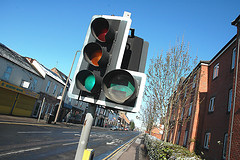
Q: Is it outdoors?
A: Yes, it is outdoors.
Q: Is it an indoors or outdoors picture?
A: It is outdoors.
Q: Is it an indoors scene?
A: No, it is outdoors.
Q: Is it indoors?
A: No, it is outdoors.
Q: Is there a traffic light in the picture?
A: Yes, there is a traffic light.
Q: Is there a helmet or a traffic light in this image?
A: Yes, there is a traffic light.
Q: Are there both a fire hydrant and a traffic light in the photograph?
A: No, there is a traffic light but no fire hydrants.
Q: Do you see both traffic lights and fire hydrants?
A: No, there is a traffic light but no fire hydrants.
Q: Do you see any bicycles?
A: No, there are no bicycles.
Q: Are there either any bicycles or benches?
A: No, there are no bicycles or benches.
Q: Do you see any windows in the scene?
A: Yes, there is a window.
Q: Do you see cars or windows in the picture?
A: Yes, there is a window.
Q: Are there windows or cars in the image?
A: Yes, there is a window.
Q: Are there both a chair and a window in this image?
A: No, there is a window but no chairs.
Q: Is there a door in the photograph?
A: No, there are no doors.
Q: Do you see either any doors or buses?
A: No, there are no doors or buses.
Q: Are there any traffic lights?
A: Yes, there is a traffic light.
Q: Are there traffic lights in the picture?
A: Yes, there is a traffic light.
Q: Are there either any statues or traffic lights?
A: Yes, there is a traffic light.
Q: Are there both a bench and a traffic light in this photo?
A: No, there is a traffic light but no benches.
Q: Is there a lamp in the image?
A: No, there are no lamps.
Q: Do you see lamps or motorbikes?
A: No, there are no lamps or motorbikes.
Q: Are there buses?
A: No, there are no buses.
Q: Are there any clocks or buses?
A: No, there are no buses or clocks.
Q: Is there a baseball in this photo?
A: No, there are no baseballs.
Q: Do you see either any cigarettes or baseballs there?
A: No, there are no baseballs or cigarettes.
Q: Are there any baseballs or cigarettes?
A: No, there are no baseballs or cigarettes.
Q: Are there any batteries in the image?
A: No, there are no batteries.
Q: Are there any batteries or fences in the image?
A: No, there are no batteries or fences.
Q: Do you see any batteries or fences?
A: No, there are no batteries or fences.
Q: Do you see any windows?
A: Yes, there is a window.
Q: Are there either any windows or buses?
A: Yes, there is a window.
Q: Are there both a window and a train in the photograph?
A: No, there is a window but no trains.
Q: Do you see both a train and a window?
A: No, there is a window but no trains.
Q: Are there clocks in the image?
A: No, there are no clocks.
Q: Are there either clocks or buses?
A: No, there are no clocks or buses.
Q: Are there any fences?
A: No, there are no fences.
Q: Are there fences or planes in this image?
A: No, there are no fences or planes.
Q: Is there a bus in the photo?
A: No, there are no buses.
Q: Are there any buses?
A: No, there are no buses.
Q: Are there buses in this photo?
A: No, there are no buses.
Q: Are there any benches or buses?
A: No, there are no buses or benches.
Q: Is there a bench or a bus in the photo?
A: No, there are no buses or benches.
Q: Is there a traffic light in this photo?
A: Yes, there is a traffic light.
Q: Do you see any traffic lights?
A: Yes, there is a traffic light.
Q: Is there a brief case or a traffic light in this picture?
A: Yes, there is a traffic light.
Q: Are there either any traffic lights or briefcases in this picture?
A: Yes, there is a traffic light.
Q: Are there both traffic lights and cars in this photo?
A: Yes, there are both a traffic light and a car.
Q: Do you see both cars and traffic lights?
A: Yes, there are both a traffic light and a car.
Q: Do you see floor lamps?
A: No, there are no floor lamps.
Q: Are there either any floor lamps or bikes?
A: No, there are no floor lamps or bikes.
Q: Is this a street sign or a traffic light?
A: This is a traffic light.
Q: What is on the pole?
A: The traffic signal is on the pole.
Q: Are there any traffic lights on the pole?
A: Yes, there is a traffic light on the pole.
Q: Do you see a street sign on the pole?
A: No, there is a traffic light on the pole.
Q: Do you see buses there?
A: No, there are no buses.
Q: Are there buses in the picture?
A: No, there are no buses.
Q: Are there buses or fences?
A: No, there are no buses or fences.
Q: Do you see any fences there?
A: No, there are no fences.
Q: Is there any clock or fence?
A: No, there are no fences or clocks.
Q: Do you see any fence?
A: No, there are no fences.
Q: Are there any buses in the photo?
A: No, there are no buses.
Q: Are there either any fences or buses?
A: No, there are no buses or fences.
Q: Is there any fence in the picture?
A: No, there are no fences.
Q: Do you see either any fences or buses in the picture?
A: No, there are no fences or buses.